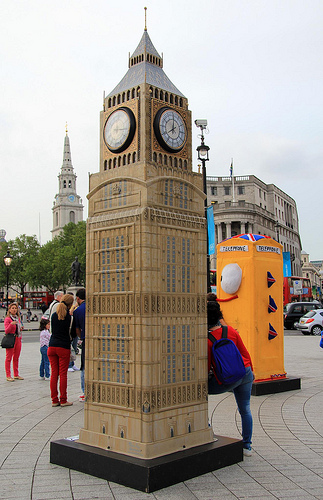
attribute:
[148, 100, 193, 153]
clock — round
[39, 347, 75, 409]
pants — red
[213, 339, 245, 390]
backpack — blue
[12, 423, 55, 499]
tile — curved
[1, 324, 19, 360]
bag — black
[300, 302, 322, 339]
car — white, parked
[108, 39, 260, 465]
clock tower — small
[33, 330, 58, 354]
shirt — pink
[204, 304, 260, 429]
person — leaning, standing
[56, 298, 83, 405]
woman — talking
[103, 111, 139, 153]
clock — white, round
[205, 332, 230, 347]
straps — black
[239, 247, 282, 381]
booth — yellow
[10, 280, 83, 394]
people — standing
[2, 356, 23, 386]
pants — red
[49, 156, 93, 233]
building — gray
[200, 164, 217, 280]
pole — black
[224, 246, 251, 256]
letters — black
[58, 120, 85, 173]
steeple — tall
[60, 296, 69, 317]
hair — blonde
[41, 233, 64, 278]
trees — green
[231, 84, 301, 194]
sky — cloudy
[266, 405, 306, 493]
ground — tile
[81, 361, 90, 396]
pants — blue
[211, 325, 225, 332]
collar — white